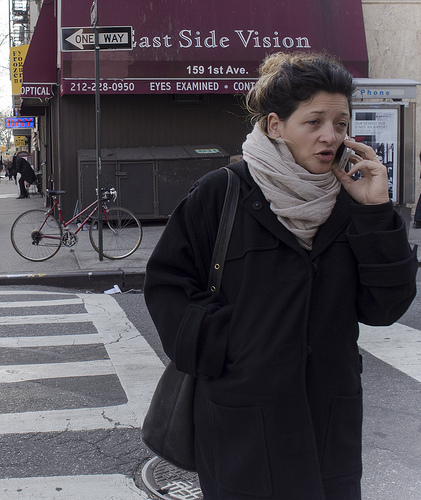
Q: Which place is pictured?
A: It is a street.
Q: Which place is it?
A: It is a street.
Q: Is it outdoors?
A: Yes, it is outdoors.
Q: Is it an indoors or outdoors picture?
A: It is outdoors.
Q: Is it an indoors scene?
A: No, it is outdoors.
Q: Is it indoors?
A: No, it is outdoors.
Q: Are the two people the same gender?
A: No, they are both male and female.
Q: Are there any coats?
A: Yes, there is a coat.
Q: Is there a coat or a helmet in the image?
A: Yes, there is a coat.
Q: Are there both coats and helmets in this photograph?
A: No, there is a coat but no helmets.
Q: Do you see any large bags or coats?
A: Yes, there is a large coat.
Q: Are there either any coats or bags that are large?
A: Yes, the coat is large.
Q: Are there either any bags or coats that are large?
A: Yes, the coat is large.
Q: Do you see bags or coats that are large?
A: Yes, the coat is large.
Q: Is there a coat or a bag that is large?
A: Yes, the coat is large.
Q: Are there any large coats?
A: Yes, there is a large coat.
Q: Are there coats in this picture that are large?
A: Yes, there is a coat that is large.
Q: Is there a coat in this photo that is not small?
A: Yes, there is a large coat.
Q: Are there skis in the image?
A: No, there are no skis.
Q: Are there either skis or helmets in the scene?
A: No, there are no skis or helmets.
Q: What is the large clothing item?
A: The clothing item is a coat.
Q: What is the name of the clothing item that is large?
A: The clothing item is a coat.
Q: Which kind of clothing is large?
A: The clothing is a coat.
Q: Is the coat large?
A: Yes, the coat is large.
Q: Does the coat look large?
A: Yes, the coat is large.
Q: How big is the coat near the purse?
A: The coat is large.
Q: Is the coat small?
A: No, the coat is large.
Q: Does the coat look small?
A: No, the coat is large.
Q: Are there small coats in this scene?
A: No, there is a coat but it is large.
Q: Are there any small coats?
A: No, there is a coat but it is large.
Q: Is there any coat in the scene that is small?
A: No, there is a coat but it is large.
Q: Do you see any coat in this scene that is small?
A: No, there is a coat but it is large.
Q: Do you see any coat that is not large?
A: No, there is a coat but it is large.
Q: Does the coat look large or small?
A: The coat is large.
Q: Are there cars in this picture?
A: No, there are no cars.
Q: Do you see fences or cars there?
A: No, there are no cars or fences.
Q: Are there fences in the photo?
A: No, there are no fences.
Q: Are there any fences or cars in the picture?
A: No, there are no fences or cars.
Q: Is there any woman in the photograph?
A: Yes, there is a woman.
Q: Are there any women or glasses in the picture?
A: Yes, there is a woman.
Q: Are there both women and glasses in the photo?
A: No, there is a woman but no glasses.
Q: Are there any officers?
A: No, there are no officers.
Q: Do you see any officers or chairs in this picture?
A: No, there are no officers or chairs.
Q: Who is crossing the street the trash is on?
A: The woman is crossing the street.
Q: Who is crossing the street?
A: The woman is crossing the street.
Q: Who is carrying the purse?
A: The woman is carrying the purse.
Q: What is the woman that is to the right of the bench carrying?
A: The woman is carrying a purse.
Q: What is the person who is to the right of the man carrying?
A: The woman is carrying a purse.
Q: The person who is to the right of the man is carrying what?
A: The woman is carrying a purse.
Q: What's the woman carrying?
A: The woman is carrying a purse.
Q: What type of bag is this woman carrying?
A: The woman is carrying a purse.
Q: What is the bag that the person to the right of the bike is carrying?
A: The bag is a purse.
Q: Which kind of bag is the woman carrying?
A: The woman is carrying a purse.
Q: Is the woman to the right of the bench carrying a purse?
A: Yes, the woman is carrying a purse.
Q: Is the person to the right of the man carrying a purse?
A: Yes, the woman is carrying a purse.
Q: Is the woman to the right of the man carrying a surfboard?
A: No, the woman is carrying a purse.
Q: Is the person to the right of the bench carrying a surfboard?
A: No, the woman is carrying a purse.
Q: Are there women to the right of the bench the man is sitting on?
A: Yes, there is a woman to the right of the bench.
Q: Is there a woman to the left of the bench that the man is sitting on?
A: No, the woman is to the right of the bench.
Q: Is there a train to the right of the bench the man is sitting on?
A: No, there is a woman to the right of the bench.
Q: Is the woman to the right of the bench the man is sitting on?
A: Yes, the woman is to the right of the bench.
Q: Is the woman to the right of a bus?
A: No, the woman is to the right of the bench.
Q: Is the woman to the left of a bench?
A: No, the woman is to the right of a bench.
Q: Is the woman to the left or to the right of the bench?
A: The woman is to the right of the bench.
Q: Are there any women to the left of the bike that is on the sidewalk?
A: No, the woman is to the right of the bike.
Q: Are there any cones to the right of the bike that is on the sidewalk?
A: No, there is a woman to the right of the bike.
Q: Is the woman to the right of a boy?
A: No, the woman is to the right of the bike.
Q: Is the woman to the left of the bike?
A: No, the woman is to the right of the bike.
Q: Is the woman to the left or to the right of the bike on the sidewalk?
A: The woman is to the right of the bike.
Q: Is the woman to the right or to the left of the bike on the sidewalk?
A: The woman is to the right of the bike.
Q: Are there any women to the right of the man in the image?
A: Yes, there is a woman to the right of the man.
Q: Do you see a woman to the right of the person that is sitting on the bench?
A: Yes, there is a woman to the right of the man.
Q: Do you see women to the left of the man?
A: No, the woman is to the right of the man.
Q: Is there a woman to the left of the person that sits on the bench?
A: No, the woman is to the right of the man.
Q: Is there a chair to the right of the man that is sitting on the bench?
A: No, there is a woman to the right of the man.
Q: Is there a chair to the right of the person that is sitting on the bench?
A: No, there is a woman to the right of the man.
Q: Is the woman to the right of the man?
A: Yes, the woman is to the right of the man.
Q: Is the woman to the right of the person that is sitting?
A: Yes, the woman is to the right of the man.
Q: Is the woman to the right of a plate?
A: No, the woman is to the right of the man.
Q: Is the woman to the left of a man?
A: No, the woman is to the right of a man.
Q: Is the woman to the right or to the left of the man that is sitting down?
A: The woman is to the right of the man.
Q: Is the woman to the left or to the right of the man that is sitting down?
A: The woman is to the right of the man.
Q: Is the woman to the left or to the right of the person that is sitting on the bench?
A: The woman is to the right of the man.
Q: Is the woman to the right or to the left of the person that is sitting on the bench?
A: The woman is to the right of the man.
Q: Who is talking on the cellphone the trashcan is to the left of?
A: The woman is talking on the mobile phone.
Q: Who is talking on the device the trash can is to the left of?
A: The woman is talking on the mobile phone.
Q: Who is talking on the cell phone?
A: The woman is talking on the mobile phone.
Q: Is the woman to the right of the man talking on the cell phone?
A: Yes, the woman is talking on the cell phone.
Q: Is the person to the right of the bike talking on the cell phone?
A: Yes, the woman is talking on the cell phone.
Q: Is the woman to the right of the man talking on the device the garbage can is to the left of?
A: Yes, the woman is talking on the cell phone.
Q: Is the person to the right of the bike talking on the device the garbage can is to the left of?
A: Yes, the woman is talking on the cell phone.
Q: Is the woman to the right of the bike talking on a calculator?
A: No, the woman is talking on the cell phone.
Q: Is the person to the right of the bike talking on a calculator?
A: No, the woman is talking on the cell phone.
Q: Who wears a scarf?
A: The woman wears a scarf.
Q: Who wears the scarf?
A: The woman wears a scarf.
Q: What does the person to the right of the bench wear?
A: The woman wears a scarf.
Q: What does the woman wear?
A: The woman wears a scarf.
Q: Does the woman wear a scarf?
A: Yes, the woman wears a scarf.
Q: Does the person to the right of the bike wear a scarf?
A: Yes, the woman wears a scarf.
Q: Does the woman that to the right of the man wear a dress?
A: No, the woman wears a scarf.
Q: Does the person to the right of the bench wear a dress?
A: No, the woman wears a scarf.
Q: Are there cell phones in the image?
A: Yes, there is a cell phone.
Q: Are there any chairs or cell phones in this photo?
A: Yes, there is a cell phone.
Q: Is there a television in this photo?
A: No, there are no televisions.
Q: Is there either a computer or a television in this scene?
A: No, there are no televisions or computers.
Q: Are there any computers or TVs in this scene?
A: No, there are no TVs or computers.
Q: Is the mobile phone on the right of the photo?
A: Yes, the mobile phone is on the right of the image.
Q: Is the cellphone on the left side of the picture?
A: No, the cellphone is on the right of the image.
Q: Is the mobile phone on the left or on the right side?
A: The mobile phone is on the right of the image.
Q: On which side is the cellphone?
A: The cellphone is on the right of the image.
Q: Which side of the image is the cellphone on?
A: The cellphone is on the right of the image.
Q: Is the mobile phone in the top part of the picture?
A: Yes, the mobile phone is in the top of the image.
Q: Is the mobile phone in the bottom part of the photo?
A: No, the mobile phone is in the top of the image.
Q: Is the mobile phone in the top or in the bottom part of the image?
A: The mobile phone is in the top of the image.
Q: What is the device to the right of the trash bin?
A: The device is a cell phone.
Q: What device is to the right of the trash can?
A: The device is a cell phone.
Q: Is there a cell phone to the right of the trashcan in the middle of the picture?
A: Yes, there is a cell phone to the right of the trash bin.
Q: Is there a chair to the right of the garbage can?
A: No, there is a cell phone to the right of the garbage can.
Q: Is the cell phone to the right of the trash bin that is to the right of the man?
A: Yes, the cell phone is to the right of the garbage can.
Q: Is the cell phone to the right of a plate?
A: No, the cell phone is to the right of the garbage can.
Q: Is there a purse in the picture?
A: Yes, there is a purse.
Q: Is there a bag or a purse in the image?
A: Yes, there is a purse.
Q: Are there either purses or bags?
A: Yes, there is a purse.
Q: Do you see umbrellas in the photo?
A: No, there are no umbrellas.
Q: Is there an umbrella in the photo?
A: No, there are no umbrellas.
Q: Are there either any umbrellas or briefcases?
A: No, there are no umbrellas or briefcases.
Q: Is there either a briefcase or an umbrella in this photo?
A: No, there are no umbrellas or briefcases.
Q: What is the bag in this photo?
A: The bag is a purse.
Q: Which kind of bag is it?
A: The bag is a purse.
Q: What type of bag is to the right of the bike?
A: The bag is a purse.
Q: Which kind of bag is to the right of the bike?
A: The bag is a purse.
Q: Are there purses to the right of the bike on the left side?
A: Yes, there is a purse to the right of the bike.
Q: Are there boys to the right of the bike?
A: No, there is a purse to the right of the bike.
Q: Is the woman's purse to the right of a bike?
A: Yes, the purse is to the right of a bike.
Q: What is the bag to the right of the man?
A: The bag is a purse.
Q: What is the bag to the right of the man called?
A: The bag is a purse.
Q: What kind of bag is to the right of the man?
A: The bag is a purse.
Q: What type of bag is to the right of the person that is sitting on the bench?
A: The bag is a purse.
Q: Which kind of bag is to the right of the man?
A: The bag is a purse.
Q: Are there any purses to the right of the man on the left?
A: Yes, there is a purse to the right of the man.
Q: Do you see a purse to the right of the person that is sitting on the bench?
A: Yes, there is a purse to the right of the man.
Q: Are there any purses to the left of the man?
A: No, the purse is to the right of the man.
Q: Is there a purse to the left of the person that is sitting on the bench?
A: No, the purse is to the right of the man.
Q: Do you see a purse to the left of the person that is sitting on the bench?
A: No, the purse is to the right of the man.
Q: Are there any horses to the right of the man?
A: No, there is a purse to the right of the man.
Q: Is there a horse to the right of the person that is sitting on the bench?
A: No, there is a purse to the right of the man.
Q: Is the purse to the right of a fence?
A: No, the purse is to the right of the man.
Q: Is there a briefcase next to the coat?
A: No, there is a purse next to the coat.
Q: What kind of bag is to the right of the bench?
A: The bag is a purse.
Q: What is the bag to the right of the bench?
A: The bag is a purse.